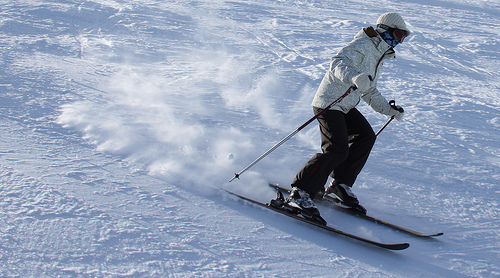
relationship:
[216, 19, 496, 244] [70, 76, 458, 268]
man on hill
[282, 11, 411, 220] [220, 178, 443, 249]
man wearing skis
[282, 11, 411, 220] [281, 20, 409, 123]
man wearing jacket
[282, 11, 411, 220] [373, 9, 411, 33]
man wearing hat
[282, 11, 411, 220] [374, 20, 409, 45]
man wearing goggles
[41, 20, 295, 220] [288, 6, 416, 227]
snow dust behind ski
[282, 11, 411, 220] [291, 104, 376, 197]
man wearing pants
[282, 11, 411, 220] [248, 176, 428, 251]
man wearing skis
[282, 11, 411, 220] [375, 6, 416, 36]
man wearing hat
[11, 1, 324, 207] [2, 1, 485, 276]
tracks in snow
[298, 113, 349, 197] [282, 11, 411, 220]
leg on man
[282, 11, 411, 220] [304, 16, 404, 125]
man wearing jacket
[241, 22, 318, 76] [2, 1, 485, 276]
marks in snow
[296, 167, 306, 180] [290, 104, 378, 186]
wrinkle in pants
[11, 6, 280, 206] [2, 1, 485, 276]
tracks in snow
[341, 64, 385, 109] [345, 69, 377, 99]
glove on hand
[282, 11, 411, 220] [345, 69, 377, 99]
man has hand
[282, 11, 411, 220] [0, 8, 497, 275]
man skiing down hill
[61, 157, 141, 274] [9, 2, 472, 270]
snow on hillside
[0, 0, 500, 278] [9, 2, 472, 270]
snow on hillside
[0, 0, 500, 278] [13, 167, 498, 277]
snow on hillside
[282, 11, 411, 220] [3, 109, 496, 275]
man skiing down hill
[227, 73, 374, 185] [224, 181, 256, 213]
pole has end